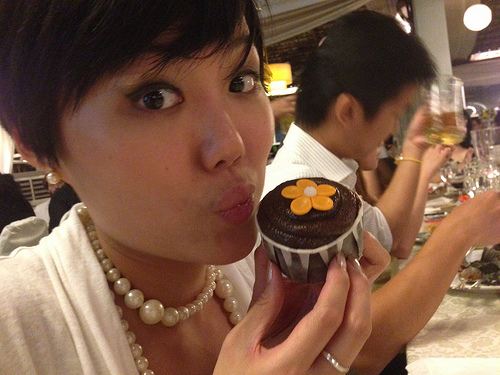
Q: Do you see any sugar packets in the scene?
A: No, there are no sugar packets.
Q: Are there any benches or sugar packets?
A: No, there are no sugar packets or benches.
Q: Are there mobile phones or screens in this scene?
A: No, there are no mobile phones or screens.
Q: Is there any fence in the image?
A: No, there are no fences.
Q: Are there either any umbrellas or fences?
A: No, there are no fences or umbrellas.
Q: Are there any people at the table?
A: Yes, there are people at the table.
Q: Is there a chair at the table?
A: No, there are people at the table.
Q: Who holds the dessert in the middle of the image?
A: The people hold the cake.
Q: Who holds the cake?
A: The people hold the cake.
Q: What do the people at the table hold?
A: The people hold the cake.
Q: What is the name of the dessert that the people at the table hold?
A: The dessert is a cake.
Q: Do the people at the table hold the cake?
A: Yes, the people hold the cake.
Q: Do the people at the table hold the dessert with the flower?
A: Yes, the people hold the cake.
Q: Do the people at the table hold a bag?
A: No, the people hold the cake.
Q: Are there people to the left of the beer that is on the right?
A: Yes, there are people to the left of the beer.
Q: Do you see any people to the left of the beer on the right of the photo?
A: Yes, there are people to the left of the beer.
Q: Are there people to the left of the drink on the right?
A: Yes, there are people to the left of the beer.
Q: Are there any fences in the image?
A: No, there are no fences.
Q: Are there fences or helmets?
A: No, there are no fences or helmets.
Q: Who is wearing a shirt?
A: The man is wearing a shirt.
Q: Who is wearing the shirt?
A: The man is wearing a shirt.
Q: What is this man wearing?
A: The man is wearing a shirt.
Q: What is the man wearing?
A: The man is wearing a shirt.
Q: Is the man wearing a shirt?
A: Yes, the man is wearing a shirt.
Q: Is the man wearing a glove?
A: No, the man is wearing a shirt.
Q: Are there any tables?
A: Yes, there is a table.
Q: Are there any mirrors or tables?
A: Yes, there is a table.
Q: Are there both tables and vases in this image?
A: No, there is a table but no vases.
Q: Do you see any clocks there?
A: No, there are no clocks.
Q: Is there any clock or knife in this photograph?
A: No, there are no clocks or knives.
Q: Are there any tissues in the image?
A: No, there are no tissues.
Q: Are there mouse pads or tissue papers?
A: No, there are no tissue papers or mouse pads.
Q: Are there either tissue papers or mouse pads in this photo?
A: No, there are no tissue papers or mouse pads.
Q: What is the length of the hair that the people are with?
A: The hair is short.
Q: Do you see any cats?
A: No, there are no cats.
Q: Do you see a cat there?
A: No, there are no cats.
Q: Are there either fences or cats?
A: No, there are no cats or fences.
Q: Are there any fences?
A: No, there are no fences.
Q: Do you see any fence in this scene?
A: No, there are no fences.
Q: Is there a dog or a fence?
A: No, there are no fences or dogs.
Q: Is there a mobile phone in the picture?
A: No, there are no cell phones.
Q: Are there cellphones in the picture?
A: No, there are no cellphones.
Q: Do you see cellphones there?
A: No, there are no cellphones.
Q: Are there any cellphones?
A: No, there are no cellphones.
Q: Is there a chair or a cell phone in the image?
A: No, there are no cell phones or chairs.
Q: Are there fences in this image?
A: No, there are no fences.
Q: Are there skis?
A: No, there are no skis.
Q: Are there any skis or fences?
A: No, there are no skis or fences.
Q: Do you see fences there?
A: No, there are no fences.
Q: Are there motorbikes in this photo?
A: No, there are no motorbikes.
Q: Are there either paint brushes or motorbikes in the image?
A: No, there are no motorbikes or paint brushes.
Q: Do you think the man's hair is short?
A: Yes, the hair is short.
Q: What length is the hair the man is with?
A: The hair is short.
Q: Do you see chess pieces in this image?
A: No, there are no chess pieces.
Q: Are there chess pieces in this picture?
A: No, there are no chess pieces.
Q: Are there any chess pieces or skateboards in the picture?
A: No, there are no chess pieces or skateboards.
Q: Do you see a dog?
A: No, there are no dogs.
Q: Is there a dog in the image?
A: No, there are no dogs.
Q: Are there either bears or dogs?
A: No, there are no dogs or bears.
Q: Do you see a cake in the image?
A: Yes, there is a cake.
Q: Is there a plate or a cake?
A: Yes, there is a cake.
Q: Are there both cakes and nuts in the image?
A: No, there is a cake but no nuts.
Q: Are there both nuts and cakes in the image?
A: No, there is a cake but no nuts.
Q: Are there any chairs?
A: No, there are no chairs.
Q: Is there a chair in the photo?
A: No, there are no chairs.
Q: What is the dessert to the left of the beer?
A: The dessert is a cake.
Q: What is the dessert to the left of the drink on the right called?
A: The dessert is a cake.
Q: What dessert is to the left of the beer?
A: The dessert is a cake.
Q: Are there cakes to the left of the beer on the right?
A: Yes, there is a cake to the left of the beer.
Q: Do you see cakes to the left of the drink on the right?
A: Yes, there is a cake to the left of the beer.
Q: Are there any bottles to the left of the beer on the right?
A: No, there is a cake to the left of the beer.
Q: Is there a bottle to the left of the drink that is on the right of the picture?
A: No, there is a cake to the left of the beer.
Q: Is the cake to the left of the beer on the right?
A: Yes, the cake is to the left of the beer.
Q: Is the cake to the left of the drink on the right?
A: Yes, the cake is to the left of the beer.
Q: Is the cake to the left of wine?
A: No, the cake is to the left of the beer.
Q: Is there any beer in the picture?
A: Yes, there is beer.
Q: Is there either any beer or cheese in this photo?
A: Yes, there is beer.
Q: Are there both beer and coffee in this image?
A: No, there is beer but no coffee.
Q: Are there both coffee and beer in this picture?
A: No, there is beer but no coffee.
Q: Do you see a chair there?
A: No, there are no chairs.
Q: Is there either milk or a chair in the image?
A: No, there are no chairs or milk.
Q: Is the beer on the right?
A: Yes, the beer is on the right of the image.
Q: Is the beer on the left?
A: No, the beer is on the right of the image.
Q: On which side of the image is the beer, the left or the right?
A: The beer is on the right of the image.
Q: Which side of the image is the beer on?
A: The beer is on the right of the image.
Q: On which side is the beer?
A: The beer is on the right of the image.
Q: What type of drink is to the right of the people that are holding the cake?
A: The drink is beer.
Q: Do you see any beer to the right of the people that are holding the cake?
A: Yes, there is beer to the right of the people.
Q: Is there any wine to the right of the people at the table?
A: No, there is beer to the right of the people.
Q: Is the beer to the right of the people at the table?
A: Yes, the beer is to the right of the people.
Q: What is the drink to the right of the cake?
A: The drink is beer.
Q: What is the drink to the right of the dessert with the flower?
A: The drink is beer.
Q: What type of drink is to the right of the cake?
A: The drink is beer.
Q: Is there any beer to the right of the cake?
A: Yes, there is beer to the right of the cake.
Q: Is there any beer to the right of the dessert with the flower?
A: Yes, there is beer to the right of the cake.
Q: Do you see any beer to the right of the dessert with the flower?
A: Yes, there is beer to the right of the cake.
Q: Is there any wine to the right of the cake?
A: No, there is beer to the right of the cake.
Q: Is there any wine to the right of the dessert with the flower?
A: No, there is beer to the right of the cake.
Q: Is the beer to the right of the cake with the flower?
A: Yes, the beer is to the right of the cake.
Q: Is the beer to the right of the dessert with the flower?
A: Yes, the beer is to the right of the cake.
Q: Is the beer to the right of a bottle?
A: No, the beer is to the right of the cake.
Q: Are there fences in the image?
A: No, there are no fences.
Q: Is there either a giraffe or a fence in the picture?
A: No, there are no fences or giraffes.